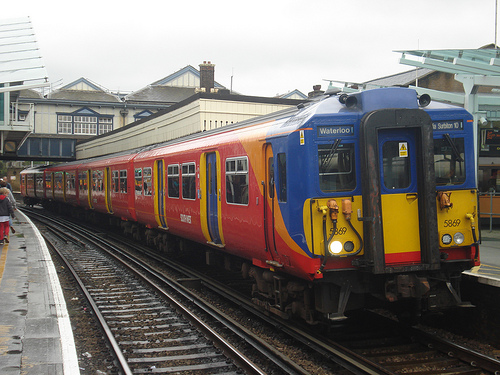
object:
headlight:
[323, 239, 343, 255]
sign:
[315, 123, 355, 137]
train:
[19, 87, 486, 328]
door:
[198, 150, 225, 242]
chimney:
[195, 61, 217, 92]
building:
[0, 14, 306, 160]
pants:
[0, 221, 12, 242]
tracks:
[16, 205, 499, 375]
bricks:
[22, 316, 62, 338]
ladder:
[269, 272, 283, 309]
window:
[54, 104, 112, 135]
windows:
[179, 163, 196, 202]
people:
[0, 196, 17, 247]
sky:
[0, 0, 499, 99]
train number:
[443, 216, 464, 227]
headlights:
[449, 232, 466, 246]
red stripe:
[263, 126, 311, 136]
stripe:
[0, 238, 10, 283]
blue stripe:
[269, 86, 477, 261]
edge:
[16, 205, 80, 374]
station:
[0, 171, 497, 374]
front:
[297, 88, 486, 331]